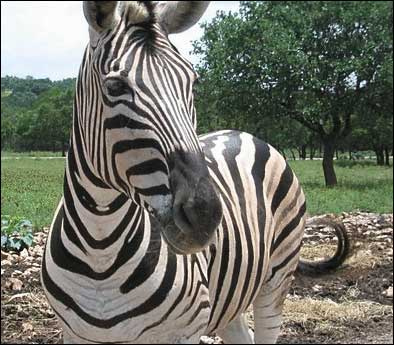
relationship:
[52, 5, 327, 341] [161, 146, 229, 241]
zebra has black nose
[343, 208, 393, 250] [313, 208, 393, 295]
rocks on dirt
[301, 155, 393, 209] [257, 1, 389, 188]
grass growing amongst trees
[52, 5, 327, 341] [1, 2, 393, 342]
zebra in photo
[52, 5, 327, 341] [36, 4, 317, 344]
zebra has stripes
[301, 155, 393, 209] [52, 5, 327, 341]
grass behind zebra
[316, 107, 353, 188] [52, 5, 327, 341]
trunk nearest zebra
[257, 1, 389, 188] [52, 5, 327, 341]
plant closest to zebra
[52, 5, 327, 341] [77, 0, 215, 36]
zebra two ears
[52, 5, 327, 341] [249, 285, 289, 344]
zebra back left leg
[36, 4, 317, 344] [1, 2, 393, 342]
animal facing camera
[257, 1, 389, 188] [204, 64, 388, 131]
trees in background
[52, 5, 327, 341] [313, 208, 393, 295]
zebra standing on dirt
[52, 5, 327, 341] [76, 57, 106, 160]
zebra has black strip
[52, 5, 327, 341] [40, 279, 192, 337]
zebra has black strip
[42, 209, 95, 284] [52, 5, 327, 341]
strip on zebra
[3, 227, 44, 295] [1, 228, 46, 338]
rocks in dirt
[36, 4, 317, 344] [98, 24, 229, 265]
animal has curious face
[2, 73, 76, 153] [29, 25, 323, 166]
hillside in distance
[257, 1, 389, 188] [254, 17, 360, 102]
plant has branches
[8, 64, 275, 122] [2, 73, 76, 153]
hill has plant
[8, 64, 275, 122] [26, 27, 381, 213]
hill in background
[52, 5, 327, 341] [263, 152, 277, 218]
zebra with grey stripes